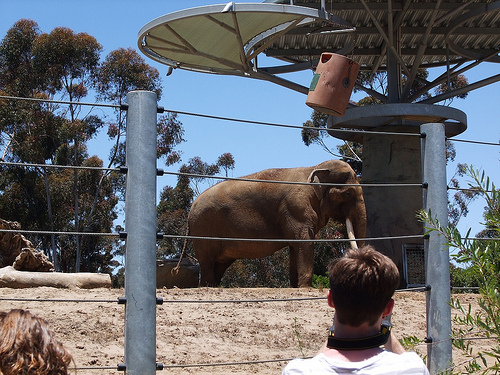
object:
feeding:
[304, 52, 360, 117]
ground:
[177, 301, 277, 364]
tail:
[170, 215, 190, 276]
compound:
[262, 195, 497, 361]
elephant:
[170, 159, 366, 288]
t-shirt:
[281, 349, 431, 374]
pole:
[124, 90, 157, 374]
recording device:
[382, 314, 392, 330]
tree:
[0, 17, 186, 272]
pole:
[419, 123, 453, 375]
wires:
[1, 95, 498, 371]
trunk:
[0, 265, 111, 289]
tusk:
[345, 218, 358, 251]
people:
[0, 243, 427, 374]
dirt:
[0, 279, 499, 375]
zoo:
[2, 0, 500, 375]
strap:
[326, 325, 392, 350]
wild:
[50, 34, 452, 275]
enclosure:
[0, 89, 499, 374]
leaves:
[11, 37, 123, 98]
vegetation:
[414, 159, 499, 374]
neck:
[327, 311, 381, 355]